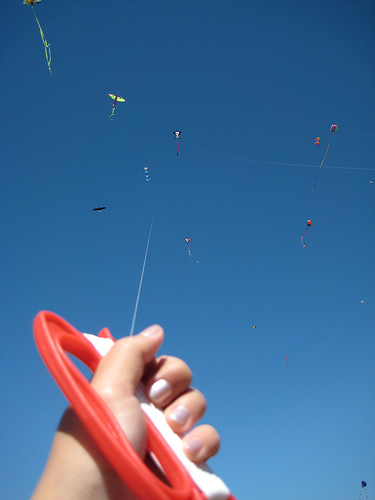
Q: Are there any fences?
A: No, there are no fences.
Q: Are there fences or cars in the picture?
A: No, there are no fences or cars.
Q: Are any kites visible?
A: Yes, there is a kite.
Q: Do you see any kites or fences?
A: Yes, there is a kite.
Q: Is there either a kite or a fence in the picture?
A: Yes, there is a kite.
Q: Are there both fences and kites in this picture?
A: No, there is a kite but no fences.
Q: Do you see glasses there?
A: No, there are no glasses.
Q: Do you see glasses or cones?
A: No, there are no glasses or cones.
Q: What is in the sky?
A: The kite is in the sky.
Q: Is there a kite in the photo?
A: Yes, there is a kite.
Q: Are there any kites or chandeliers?
A: Yes, there is a kite.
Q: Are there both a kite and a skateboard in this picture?
A: No, there is a kite but no skateboards.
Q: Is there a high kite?
A: Yes, there is a high kite.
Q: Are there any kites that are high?
A: Yes, there is a kite that is high.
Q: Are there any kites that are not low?
A: Yes, there is a high kite.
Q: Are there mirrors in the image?
A: No, there are no mirrors.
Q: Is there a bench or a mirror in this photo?
A: No, there are no mirrors or benches.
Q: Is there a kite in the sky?
A: Yes, there is a kite in the sky.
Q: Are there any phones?
A: No, there are no phones.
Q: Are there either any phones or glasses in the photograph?
A: No, there are no phones or glasses.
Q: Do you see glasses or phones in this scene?
A: No, there are no phones or glasses.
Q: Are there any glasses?
A: No, there are no glasses.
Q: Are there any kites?
A: Yes, there is a kite.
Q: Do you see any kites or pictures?
A: Yes, there is a kite.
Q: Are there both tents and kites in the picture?
A: No, there is a kite but no tents.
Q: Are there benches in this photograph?
A: No, there are no benches.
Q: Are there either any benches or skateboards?
A: No, there are no benches or skateboards.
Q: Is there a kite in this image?
A: Yes, there is a kite.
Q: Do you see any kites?
A: Yes, there is a kite.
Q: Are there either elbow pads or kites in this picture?
A: Yes, there is a kite.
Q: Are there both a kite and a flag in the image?
A: No, there is a kite but no flags.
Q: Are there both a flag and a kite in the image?
A: No, there is a kite but no flags.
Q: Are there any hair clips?
A: No, there are no hair clips.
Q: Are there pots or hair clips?
A: No, there are no hair clips or pots.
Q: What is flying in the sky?
A: The kite is flying in the sky.